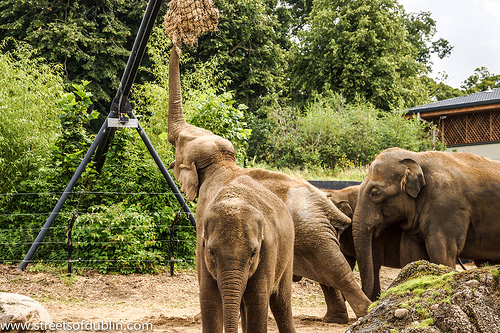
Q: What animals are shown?
A: Elephant.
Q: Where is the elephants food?
A: Hanging.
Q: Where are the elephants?
A: Enclosure.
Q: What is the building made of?
A: Wood.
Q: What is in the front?
A: An elephant.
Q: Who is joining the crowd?
A: An elephant.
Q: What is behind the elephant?
A: Trees.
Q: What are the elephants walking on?
A: Dirt.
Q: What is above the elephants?
A: A pole.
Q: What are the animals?
A: Elephants.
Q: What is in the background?
A: Tall trees.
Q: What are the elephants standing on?
A: Brown dirt.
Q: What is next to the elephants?
A: A mossy rock.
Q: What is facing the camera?
A: A baby elephant.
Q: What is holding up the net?
A: A metal stand and pole.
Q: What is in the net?
A: Elephant food.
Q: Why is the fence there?
A: To keep elephants in.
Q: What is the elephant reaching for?
A: Food.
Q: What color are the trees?
A: Green.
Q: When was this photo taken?
A: In the daytime.